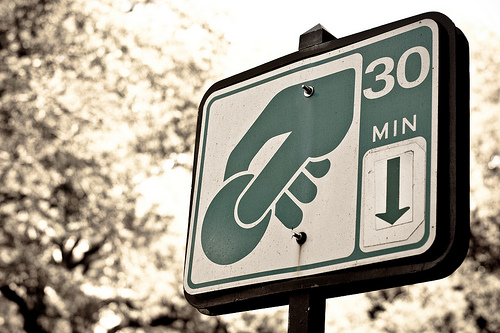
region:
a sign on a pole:
[148, 5, 465, 297]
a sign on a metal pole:
[175, 28, 497, 297]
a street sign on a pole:
[166, 23, 480, 314]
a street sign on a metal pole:
[155, 19, 497, 330]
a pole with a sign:
[82, 6, 433, 332]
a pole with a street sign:
[114, 20, 427, 330]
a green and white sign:
[171, 1, 499, 291]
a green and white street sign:
[124, 19, 476, 328]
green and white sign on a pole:
[159, 4, 494, 294]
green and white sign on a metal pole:
[157, 7, 496, 326]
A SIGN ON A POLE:
[121, 9, 499, 324]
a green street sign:
[172, 8, 444, 329]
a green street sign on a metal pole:
[133, 2, 434, 323]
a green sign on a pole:
[157, 2, 497, 322]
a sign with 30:
[148, 35, 494, 330]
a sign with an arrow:
[136, 5, 491, 325]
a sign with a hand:
[160, 10, 478, 330]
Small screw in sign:
[281, 217, 333, 261]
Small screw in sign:
[287, 80, 324, 112]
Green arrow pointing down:
[368, 153, 427, 235]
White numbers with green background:
[362, 53, 444, 95]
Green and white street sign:
[172, 33, 471, 307]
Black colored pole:
[267, 288, 344, 331]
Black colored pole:
[282, 8, 349, 57]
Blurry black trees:
[35, 41, 130, 226]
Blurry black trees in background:
[5, 261, 86, 331]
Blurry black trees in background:
[441, 225, 484, 325]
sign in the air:
[177, 44, 455, 264]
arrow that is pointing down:
[368, 160, 421, 229]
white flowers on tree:
[75, 210, 132, 259]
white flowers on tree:
[97, 174, 119, 200]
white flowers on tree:
[100, 118, 134, 149]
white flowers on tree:
[417, 303, 472, 327]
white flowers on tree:
[18, 264, 55, 304]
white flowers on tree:
[117, 141, 144, 168]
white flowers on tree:
[334, 310, 374, 327]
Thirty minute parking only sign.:
[180, 10, 470, 330]